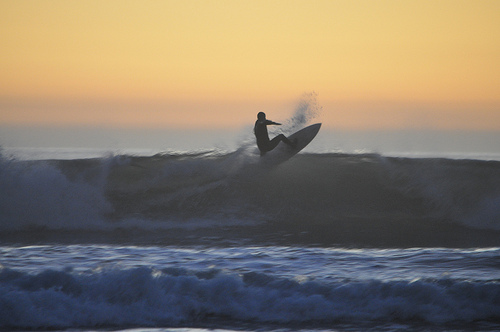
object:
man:
[253, 111, 292, 154]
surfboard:
[261, 121, 323, 168]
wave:
[10, 148, 493, 209]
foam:
[11, 171, 82, 217]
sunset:
[23, 8, 492, 87]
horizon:
[10, 120, 250, 131]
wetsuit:
[253, 120, 289, 152]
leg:
[272, 133, 290, 145]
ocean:
[8, 249, 496, 328]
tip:
[318, 121, 323, 125]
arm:
[267, 120, 279, 126]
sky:
[0, 0, 500, 47]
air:
[321, 130, 343, 153]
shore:
[118, 326, 257, 332]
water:
[287, 91, 326, 125]